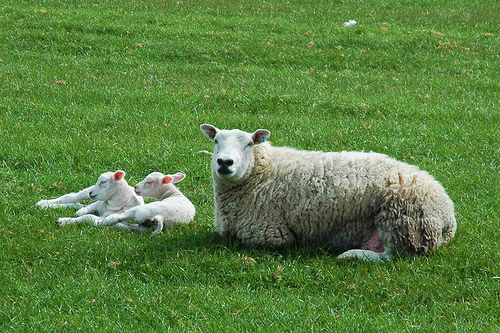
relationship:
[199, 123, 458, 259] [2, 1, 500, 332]
sheep on top of grass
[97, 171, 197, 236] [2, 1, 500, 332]
sheep on top of grass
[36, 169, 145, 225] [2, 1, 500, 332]
sheep on top of grass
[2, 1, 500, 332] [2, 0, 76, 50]
grass has part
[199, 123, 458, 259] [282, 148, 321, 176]
sheep has part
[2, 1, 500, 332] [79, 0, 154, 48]
grass has part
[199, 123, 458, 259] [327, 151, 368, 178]
sheep has part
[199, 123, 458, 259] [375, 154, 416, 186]
sheep has part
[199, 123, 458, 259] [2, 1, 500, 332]
sheep laying on grass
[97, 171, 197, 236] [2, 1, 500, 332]
sheep laying on grass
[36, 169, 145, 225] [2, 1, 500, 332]
sheep laying on grass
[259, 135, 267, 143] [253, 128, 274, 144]
tag hanging on ear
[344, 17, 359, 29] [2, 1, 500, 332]
plant growing in grass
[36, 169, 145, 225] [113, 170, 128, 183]
sheep has ear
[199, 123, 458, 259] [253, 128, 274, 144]
sheep has ear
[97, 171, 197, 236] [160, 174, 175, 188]
sheep has ear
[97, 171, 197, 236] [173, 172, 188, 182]
sheep has ear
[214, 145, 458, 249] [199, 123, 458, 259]
fur on top of sheep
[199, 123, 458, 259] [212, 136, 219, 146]
sheep has eye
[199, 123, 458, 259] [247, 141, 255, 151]
sheep has eye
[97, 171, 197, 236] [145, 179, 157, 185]
sheep has eye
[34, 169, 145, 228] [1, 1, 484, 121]
sheep lying in field